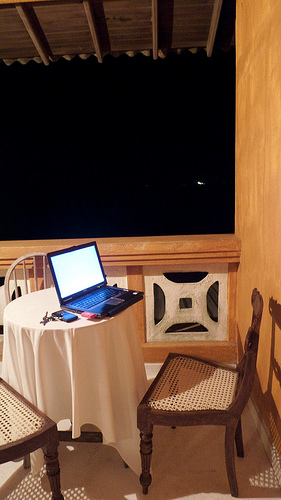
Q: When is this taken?
A: During the night.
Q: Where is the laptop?
A: On the table.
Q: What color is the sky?
A: Black.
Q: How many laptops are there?
A: One.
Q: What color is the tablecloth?
A: White.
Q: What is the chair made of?
A: Wood.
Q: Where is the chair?
A: By the table.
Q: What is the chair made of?
A: Wood.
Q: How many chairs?
A: Three.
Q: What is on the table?
A: Computer.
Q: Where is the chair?
A: At the table.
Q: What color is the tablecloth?
A: White.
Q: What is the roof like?
A: Dark wood.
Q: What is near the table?
A: Wooden chairs.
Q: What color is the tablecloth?
A: White.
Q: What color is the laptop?
A: Black.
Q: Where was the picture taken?
A: On a balcony.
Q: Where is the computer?
A: On the table.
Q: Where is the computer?
A: On the table.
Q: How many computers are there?
A: One.